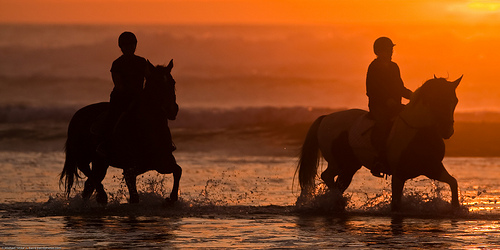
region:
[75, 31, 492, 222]
two people on horses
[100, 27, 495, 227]
two people on horses in water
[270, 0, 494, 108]
sun is setting in photograph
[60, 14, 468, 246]
two horses walking in water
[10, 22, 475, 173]
waves in background of photo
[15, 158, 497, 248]
horses feet making splashes in water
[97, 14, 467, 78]
two people wearing riding helmets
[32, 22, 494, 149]
two people riding horses together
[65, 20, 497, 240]
one horse in front of the other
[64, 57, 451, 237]
horses walking in calm water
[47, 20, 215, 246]
a horse in the water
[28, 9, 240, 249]
a person riding a horse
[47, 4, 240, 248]
a person riding a horse in the water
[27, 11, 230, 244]
a horse walking in the water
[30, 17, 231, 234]
a horse at sunset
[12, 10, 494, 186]
two horses at sunset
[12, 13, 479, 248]
two horses walking in the water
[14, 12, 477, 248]
two people riding two horses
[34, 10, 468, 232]
horses walking next to each other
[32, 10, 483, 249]
two horses walking in the water together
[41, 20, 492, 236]
Two people riding horses.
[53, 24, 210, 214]
This person can barely be seen.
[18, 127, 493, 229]
The horses are in the water.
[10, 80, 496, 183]
Waves are in the background.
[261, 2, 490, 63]
This is at sunset.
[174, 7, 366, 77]
The sky is orange.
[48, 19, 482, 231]
The horses don't seem to mind the water.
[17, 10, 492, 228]
This is at a beach.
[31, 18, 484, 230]
The horses are making the water splash.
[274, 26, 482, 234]
This horse is brown and white.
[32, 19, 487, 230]
two people riding horses in the water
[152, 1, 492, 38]
orange colored sky in the background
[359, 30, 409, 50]
helmet on a person riding horse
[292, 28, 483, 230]
person riding horse in the front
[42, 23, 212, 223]
person riding horse in the back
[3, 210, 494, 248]
water where people are riding horses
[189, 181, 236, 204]
water splashing from the horses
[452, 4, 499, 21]
yellow sun in the sky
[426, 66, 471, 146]
face of a horse in the dark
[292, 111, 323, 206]
tail of a horse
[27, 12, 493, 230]
people riding horses in the water at sunset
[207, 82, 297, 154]
wave of water in the distance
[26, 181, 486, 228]
horses feet splashing water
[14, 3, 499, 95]
the sky at sunset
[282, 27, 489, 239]
individual riding a horse in the water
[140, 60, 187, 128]
forward facing head of a horse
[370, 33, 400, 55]
shadow of a helmet on a head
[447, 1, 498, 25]
sun in the sky at sunset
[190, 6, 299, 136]
waves in the distance